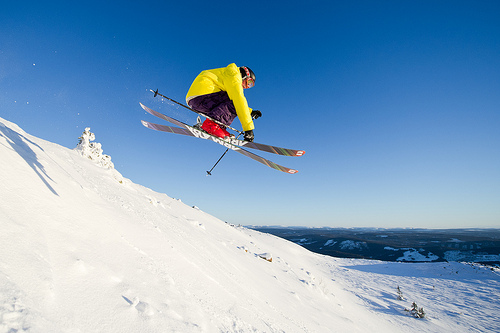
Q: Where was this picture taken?
A: It was taken in the snow mountains.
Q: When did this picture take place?
A: It took place in the day time.